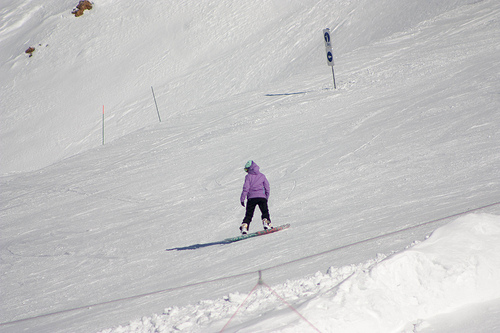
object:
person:
[236, 158, 273, 237]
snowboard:
[222, 220, 294, 243]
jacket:
[237, 160, 270, 205]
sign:
[321, 28, 335, 64]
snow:
[1, 0, 499, 331]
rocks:
[22, 45, 36, 56]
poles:
[148, 86, 168, 122]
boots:
[260, 218, 276, 233]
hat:
[240, 160, 258, 170]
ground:
[0, 0, 498, 332]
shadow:
[163, 240, 227, 252]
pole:
[329, 68, 336, 90]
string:
[259, 281, 322, 333]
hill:
[0, 0, 499, 331]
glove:
[241, 200, 246, 209]